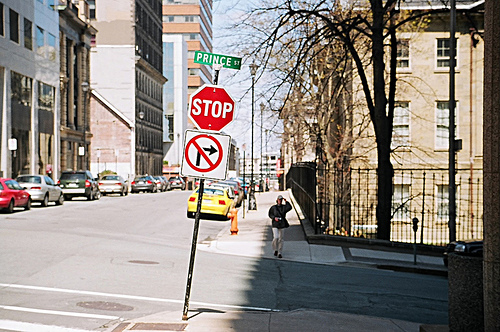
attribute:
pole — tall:
[245, 54, 264, 213]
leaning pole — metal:
[166, 31, 248, 325]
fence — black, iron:
[319, 161, 456, 236]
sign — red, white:
[191, 83, 238, 135]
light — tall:
[242, 68, 297, 259]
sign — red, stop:
[190, 83, 235, 133]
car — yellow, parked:
[187, 186, 233, 219]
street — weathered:
[2, 178, 254, 327]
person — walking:
[268, 194, 291, 258]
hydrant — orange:
[227, 206, 238, 234]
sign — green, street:
[194, 48, 241, 72]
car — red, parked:
[0, 175, 32, 214]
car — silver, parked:
[12, 174, 63, 206]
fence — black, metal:
[281, 164, 489, 255]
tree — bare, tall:
[348, 0, 434, 241]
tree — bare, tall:
[310, 2, 365, 233]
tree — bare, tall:
[280, 82, 310, 186]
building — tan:
[318, 7, 484, 242]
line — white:
[2, 278, 281, 314]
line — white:
[0, 300, 120, 324]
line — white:
[0, 316, 92, 332]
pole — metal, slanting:
[184, 73, 219, 323]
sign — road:
[192, 51, 243, 73]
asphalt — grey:
[7, 184, 464, 331]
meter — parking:
[408, 219, 419, 266]